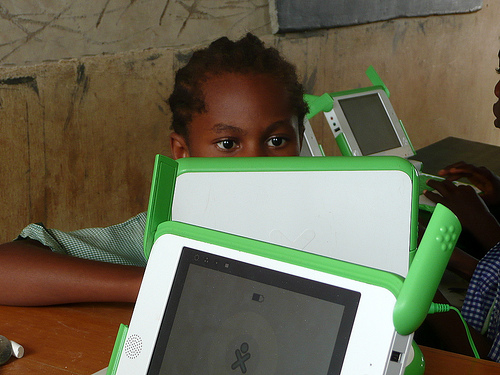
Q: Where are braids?
A: Child's head.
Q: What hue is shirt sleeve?
A: White.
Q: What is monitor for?
A: Computer.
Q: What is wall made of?
A: Cement.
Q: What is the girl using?
A: A laptop.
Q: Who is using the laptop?
A: The girl.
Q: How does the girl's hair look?
A: Short.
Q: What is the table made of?
A: Wood.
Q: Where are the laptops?
A: On the table.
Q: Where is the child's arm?
A: On the table.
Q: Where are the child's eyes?
A: Just above the green border of a laptop.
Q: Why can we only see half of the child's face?
A: The rest is obstructed by a pair of laptops.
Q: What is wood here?
A: The table.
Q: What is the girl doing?
A: Using the laptop.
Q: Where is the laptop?
A: On the table.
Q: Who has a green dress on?
A: The girl.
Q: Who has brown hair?
A: The girl.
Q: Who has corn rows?
A: The girl.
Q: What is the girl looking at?
A: The laptop.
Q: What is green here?
A: The laptop.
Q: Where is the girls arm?
A: On the table.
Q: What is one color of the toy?
A: Green.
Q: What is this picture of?
A: A boy and a toy.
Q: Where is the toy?
A: On the table.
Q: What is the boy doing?
A: He is looking the toy.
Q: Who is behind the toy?
A: A little boy.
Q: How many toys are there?
A: Two.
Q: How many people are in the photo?
A: One.